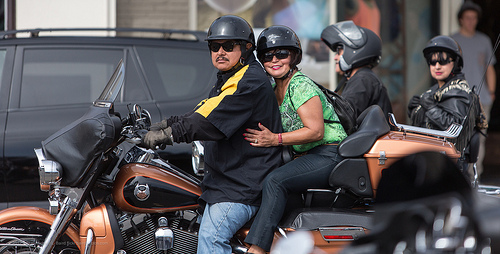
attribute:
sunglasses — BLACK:
[260, 47, 290, 66]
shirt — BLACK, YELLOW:
[170, 61, 289, 208]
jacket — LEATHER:
[408, 80, 485, 168]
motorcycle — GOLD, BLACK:
[7, 56, 469, 244]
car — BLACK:
[4, 23, 233, 194]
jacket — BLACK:
[336, 72, 391, 139]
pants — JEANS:
[188, 204, 253, 249]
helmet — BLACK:
[203, 13, 255, 43]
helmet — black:
[314, 18, 383, 71]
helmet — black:
[421, 34, 473, 61]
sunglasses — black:
[201, 36, 256, 62]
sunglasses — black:
[262, 43, 295, 65]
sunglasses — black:
[421, 49, 459, 69]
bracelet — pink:
[270, 127, 285, 152]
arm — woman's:
[241, 79, 325, 148]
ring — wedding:
[253, 134, 262, 148]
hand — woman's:
[237, 123, 280, 153]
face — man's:
[208, 35, 248, 72]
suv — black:
[4, 25, 253, 210]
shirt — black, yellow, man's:
[162, 61, 296, 217]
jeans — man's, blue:
[191, 193, 255, 253]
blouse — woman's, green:
[274, 72, 348, 162]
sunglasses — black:
[259, 45, 299, 64]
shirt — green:
[270, 73, 346, 157]